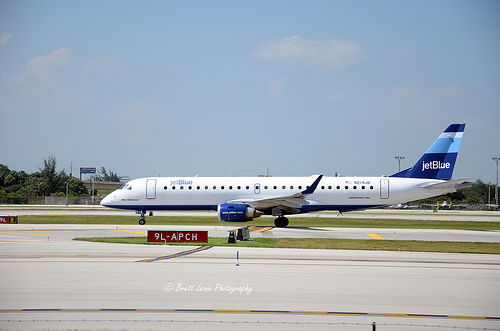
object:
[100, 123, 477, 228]
airplane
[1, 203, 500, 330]
ground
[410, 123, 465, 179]
stripes on tail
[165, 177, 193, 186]
name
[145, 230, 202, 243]
sign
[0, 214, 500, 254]
grass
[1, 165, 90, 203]
trees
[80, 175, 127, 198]
building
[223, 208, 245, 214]
white writing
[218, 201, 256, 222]
blue engine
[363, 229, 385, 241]
yellow lines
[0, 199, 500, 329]
grey pavement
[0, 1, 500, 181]
cloud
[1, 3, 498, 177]
sky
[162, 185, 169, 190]
window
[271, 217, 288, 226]
wheel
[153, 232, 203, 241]
white letters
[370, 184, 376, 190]
window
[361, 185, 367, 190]
window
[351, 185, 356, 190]
window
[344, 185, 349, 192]
window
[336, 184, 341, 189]
window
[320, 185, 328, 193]
window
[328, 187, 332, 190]
window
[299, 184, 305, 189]
window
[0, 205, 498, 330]
runway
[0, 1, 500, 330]
airport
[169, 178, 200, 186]
jetblue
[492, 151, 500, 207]
light pole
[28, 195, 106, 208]
fence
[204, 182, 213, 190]
windows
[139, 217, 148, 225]
tire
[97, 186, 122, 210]
nose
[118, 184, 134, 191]
cockpit windows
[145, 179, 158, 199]
door